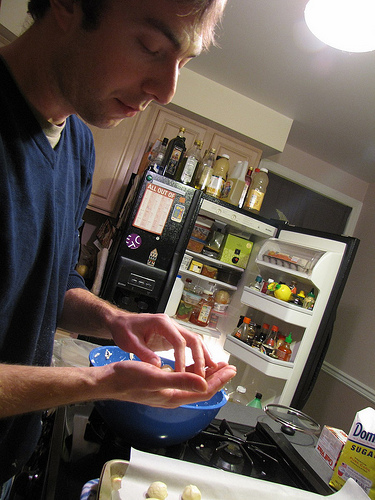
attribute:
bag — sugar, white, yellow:
[325, 412, 374, 492]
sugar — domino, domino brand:
[326, 403, 374, 492]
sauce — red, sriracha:
[275, 343, 289, 360]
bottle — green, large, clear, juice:
[278, 332, 297, 362]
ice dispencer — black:
[110, 258, 170, 311]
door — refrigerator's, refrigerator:
[88, 163, 209, 340]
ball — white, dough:
[148, 480, 172, 496]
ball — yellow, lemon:
[271, 282, 292, 300]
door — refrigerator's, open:
[208, 208, 366, 428]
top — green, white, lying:
[272, 281, 283, 290]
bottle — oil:
[217, 143, 250, 207]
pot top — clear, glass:
[260, 399, 326, 440]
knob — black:
[277, 426, 296, 435]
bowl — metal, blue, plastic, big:
[86, 340, 226, 445]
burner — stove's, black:
[86, 403, 211, 460]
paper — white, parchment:
[118, 436, 374, 499]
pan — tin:
[94, 456, 149, 500]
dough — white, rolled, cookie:
[157, 365, 182, 392]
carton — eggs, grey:
[257, 247, 316, 274]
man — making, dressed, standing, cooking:
[2, 0, 246, 495]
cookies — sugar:
[146, 474, 210, 499]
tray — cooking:
[94, 458, 130, 497]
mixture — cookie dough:
[120, 364, 204, 403]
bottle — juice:
[243, 159, 275, 212]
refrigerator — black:
[92, 170, 366, 410]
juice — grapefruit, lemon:
[242, 173, 269, 213]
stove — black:
[49, 395, 328, 498]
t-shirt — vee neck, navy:
[4, 49, 98, 483]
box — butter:
[314, 423, 353, 471]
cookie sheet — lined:
[97, 443, 364, 498]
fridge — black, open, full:
[90, 164, 363, 413]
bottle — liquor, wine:
[192, 145, 217, 192]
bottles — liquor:
[142, 116, 271, 216]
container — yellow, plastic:
[273, 281, 290, 301]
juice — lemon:
[275, 286, 291, 302]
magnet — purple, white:
[123, 231, 145, 252]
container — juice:
[204, 148, 236, 199]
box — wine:
[218, 232, 260, 271]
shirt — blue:
[0, 51, 97, 482]